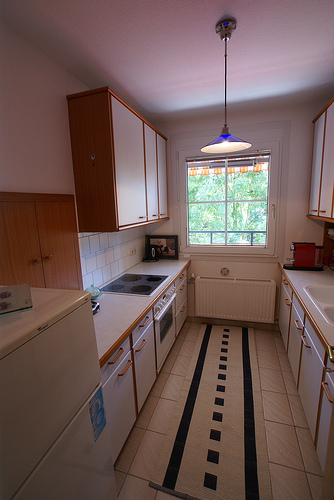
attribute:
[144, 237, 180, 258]
frame — black, picture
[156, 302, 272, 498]
rug — long, black/white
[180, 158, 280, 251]
window — white, four paned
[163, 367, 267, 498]
rug — black, tan, patterned, area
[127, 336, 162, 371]
handle — wooden, brown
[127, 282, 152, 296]
burner — four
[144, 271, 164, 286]
burner — four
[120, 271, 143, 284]
burner — four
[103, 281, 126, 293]
burner — four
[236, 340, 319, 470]
tiles — brown, rough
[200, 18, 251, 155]
light — hanging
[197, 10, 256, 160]
light — low, down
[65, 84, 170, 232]
cabinets — wooden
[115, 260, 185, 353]
oven — white, built in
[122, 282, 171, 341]
oven — white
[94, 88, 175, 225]
cabinet door — white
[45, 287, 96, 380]
freezer — white, refrigerator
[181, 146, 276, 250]
window — single, white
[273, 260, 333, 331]
basin — white, sink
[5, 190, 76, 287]
cabinet — brown, wooden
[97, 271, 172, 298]
stove top — black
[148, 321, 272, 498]
rug — black, white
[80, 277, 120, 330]
glass — small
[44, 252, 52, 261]
door knob — wooden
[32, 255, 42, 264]
door knob — wooden